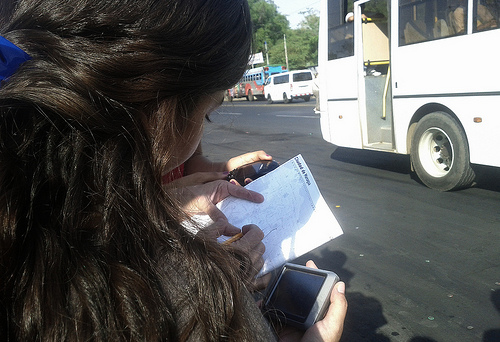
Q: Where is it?
A: This is at the pavement.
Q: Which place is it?
A: It is a pavement.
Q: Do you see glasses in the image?
A: No, there are no glasses.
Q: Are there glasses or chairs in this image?
A: No, there are no glasses or chairs.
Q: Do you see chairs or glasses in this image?
A: No, there are no glasses or chairs.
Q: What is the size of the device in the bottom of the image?
A: The device is small.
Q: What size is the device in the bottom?
A: The device is small.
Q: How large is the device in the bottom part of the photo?
A: The device is small.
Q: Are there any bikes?
A: No, there are no bikes.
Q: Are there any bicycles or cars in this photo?
A: No, there are no bicycles or cars.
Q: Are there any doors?
A: Yes, there is a door.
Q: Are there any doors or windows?
A: Yes, there is a door.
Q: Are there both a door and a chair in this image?
A: No, there is a door but no chairs.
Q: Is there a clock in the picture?
A: No, there are no clocks.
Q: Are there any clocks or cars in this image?
A: No, there are no clocks or cars.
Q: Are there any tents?
A: No, there are no tents.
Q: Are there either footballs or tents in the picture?
A: No, there are no tents or footballs.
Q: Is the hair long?
A: Yes, the hair is long.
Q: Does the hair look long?
A: Yes, the hair is long.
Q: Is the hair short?
A: No, the hair is long.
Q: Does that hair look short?
A: No, the hair is long.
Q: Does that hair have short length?
A: No, the hair is long.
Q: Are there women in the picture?
A: Yes, there is a woman.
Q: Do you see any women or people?
A: Yes, there is a woman.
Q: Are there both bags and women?
A: No, there is a woman but no bags.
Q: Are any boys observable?
A: No, there are no boys.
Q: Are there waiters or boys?
A: No, there are no boys or waiters.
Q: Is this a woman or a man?
A: This is a woman.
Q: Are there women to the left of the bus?
A: Yes, there is a woman to the left of the bus.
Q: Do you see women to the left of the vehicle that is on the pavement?
A: Yes, there is a woman to the left of the bus.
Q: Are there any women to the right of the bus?
A: No, the woman is to the left of the bus.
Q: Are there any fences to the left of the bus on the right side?
A: No, there is a woman to the left of the bus.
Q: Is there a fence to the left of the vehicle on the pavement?
A: No, there is a woman to the left of the bus.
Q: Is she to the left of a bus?
A: Yes, the woman is to the left of a bus.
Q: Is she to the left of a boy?
A: No, the woman is to the left of a bus.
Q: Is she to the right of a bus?
A: No, the woman is to the left of a bus.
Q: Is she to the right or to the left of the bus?
A: The woman is to the left of the bus.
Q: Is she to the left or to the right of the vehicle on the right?
A: The woman is to the left of the bus.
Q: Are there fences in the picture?
A: No, there are no fences.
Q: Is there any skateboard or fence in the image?
A: No, there are no fences or skateboards.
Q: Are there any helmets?
A: No, there are no helmets.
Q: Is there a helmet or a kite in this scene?
A: No, there are no helmets or kites.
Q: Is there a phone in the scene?
A: Yes, there is a phone.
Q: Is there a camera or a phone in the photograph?
A: Yes, there is a phone.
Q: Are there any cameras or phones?
A: Yes, there is a phone.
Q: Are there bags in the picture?
A: No, there are no bags.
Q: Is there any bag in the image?
A: No, there are no bags.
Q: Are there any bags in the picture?
A: No, there are no bags.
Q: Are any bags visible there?
A: No, there are no bags.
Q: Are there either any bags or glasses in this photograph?
A: No, there are no bags or glasses.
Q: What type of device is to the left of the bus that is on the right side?
A: The device is a phone.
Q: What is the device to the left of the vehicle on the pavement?
A: The device is a phone.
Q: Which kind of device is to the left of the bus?
A: The device is a phone.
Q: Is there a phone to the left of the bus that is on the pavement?
A: Yes, there is a phone to the left of the bus.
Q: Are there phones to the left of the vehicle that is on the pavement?
A: Yes, there is a phone to the left of the bus.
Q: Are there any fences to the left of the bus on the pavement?
A: No, there is a phone to the left of the bus.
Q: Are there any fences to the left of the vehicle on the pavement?
A: No, there is a phone to the left of the bus.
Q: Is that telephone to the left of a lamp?
A: No, the telephone is to the left of the bus.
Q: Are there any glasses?
A: No, there are no glasses.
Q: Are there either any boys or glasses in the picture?
A: No, there are no glasses or boys.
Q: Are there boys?
A: No, there are no boys.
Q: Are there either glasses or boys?
A: No, there are no boys or glasses.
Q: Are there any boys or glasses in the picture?
A: No, there are no boys or glasses.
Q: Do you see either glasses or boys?
A: No, there are no boys or glasses.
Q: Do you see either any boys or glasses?
A: No, there are no boys or glasses.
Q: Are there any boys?
A: No, there are no boys.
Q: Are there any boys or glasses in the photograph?
A: No, there are no boys or glasses.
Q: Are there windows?
A: Yes, there is a window.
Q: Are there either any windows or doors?
A: Yes, there is a window.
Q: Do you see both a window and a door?
A: Yes, there are both a window and a door.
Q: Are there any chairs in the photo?
A: No, there are no chairs.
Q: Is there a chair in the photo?
A: No, there are no chairs.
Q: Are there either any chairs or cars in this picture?
A: No, there are no chairs or cars.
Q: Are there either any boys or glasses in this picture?
A: No, there are no boys or glasses.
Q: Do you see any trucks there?
A: No, there are no trucks.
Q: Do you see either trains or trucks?
A: No, there are no trucks or trains.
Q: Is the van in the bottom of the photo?
A: No, the van is in the top of the image.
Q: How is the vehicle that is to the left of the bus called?
A: The vehicle is a van.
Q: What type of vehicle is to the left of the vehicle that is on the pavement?
A: The vehicle is a van.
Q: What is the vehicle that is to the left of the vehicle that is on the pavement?
A: The vehicle is a van.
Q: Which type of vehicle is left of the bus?
A: The vehicle is a van.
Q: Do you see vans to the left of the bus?
A: Yes, there is a van to the left of the bus.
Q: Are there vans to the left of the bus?
A: Yes, there is a van to the left of the bus.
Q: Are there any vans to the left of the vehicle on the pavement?
A: Yes, there is a van to the left of the bus.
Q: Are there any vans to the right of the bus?
A: No, the van is to the left of the bus.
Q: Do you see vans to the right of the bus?
A: No, the van is to the left of the bus.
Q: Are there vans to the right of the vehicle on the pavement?
A: No, the van is to the left of the bus.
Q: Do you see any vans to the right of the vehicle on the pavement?
A: No, the van is to the left of the bus.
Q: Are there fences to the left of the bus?
A: No, there is a van to the left of the bus.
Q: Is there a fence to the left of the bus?
A: No, there is a van to the left of the bus.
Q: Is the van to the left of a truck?
A: No, the van is to the left of a bus.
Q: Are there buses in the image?
A: Yes, there is a bus.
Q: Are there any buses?
A: Yes, there is a bus.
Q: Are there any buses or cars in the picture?
A: Yes, there is a bus.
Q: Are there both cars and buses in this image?
A: No, there is a bus but no cars.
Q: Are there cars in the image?
A: No, there are no cars.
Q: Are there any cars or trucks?
A: No, there are no cars or trucks.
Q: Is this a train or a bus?
A: This is a bus.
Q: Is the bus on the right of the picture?
A: Yes, the bus is on the right of the image.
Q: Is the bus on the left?
A: No, the bus is on the right of the image.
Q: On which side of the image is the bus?
A: The bus is on the right of the image.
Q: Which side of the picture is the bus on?
A: The bus is on the right of the image.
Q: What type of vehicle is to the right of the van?
A: The vehicle is a bus.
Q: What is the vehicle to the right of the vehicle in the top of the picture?
A: The vehicle is a bus.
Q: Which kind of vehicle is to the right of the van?
A: The vehicle is a bus.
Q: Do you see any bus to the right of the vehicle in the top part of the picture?
A: Yes, there is a bus to the right of the van.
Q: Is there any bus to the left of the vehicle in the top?
A: No, the bus is to the right of the van.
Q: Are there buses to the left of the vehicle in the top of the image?
A: No, the bus is to the right of the van.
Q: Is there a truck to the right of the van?
A: No, there is a bus to the right of the van.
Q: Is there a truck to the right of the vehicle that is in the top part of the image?
A: No, there is a bus to the right of the van.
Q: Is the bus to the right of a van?
A: Yes, the bus is to the right of a van.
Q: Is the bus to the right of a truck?
A: No, the bus is to the right of a van.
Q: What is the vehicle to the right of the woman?
A: The vehicle is a bus.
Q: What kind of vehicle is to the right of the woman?
A: The vehicle is a bus.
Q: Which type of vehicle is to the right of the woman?
A: The vehicle is a bus.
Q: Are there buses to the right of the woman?
A: Yes, there is a bus to the right of the woman.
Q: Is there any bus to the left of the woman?
A: No, the bus is to the right of the woman.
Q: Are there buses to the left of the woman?
A: No, the bus is to the right of the woman.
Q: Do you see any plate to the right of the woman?
A: No, there is a bus to the right of the woman.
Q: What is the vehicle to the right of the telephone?
A: The vehicle is a bus.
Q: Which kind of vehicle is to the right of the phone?
A: The vehicle is a bus.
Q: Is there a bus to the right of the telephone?
A: Yes, there is a bus to the right of the telephone.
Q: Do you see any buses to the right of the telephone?
A: Yes, there is a bus to the right of the telephone.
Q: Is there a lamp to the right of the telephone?
A: No, there is a bus to the right of the telephone.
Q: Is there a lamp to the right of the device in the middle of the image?
A: No, there is a bus to the right of the telephone.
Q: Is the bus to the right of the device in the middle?
A: Yes, the bus is to the right of the telephone.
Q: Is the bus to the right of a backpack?
A: No, the bus is to the right of the telephone.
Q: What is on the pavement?
A: The bus is on the pavement.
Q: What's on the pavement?
A: The bus is on the pavement.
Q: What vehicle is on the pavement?
A: The vehicle is a bus.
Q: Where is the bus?
A: The bus is on the pavement.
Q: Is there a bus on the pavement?
A: Yes, there is a bus on the pavement.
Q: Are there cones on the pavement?
A: No, there is a bus on the pavement.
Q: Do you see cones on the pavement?
A: No, there is a bus on the pavement.